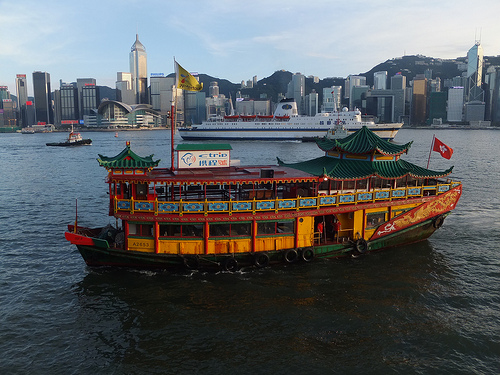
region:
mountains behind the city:
[55, 72, 490, 117]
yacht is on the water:
[187, 105, 406, 147]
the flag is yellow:
[173, 56, 203, 101]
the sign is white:
[174, 150, 228, 163]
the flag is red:
[436, 135, 456, 165]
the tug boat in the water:
[46, 125, 102, 161]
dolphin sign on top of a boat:
[167, 141, 243, 173]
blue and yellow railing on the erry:
[109, 187, 438, 203]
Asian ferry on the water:
[30, 55, 473, 296]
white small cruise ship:
[180, 83, 432, 150]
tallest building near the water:
[119, 28, 172, 127]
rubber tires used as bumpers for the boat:
[163, 231, 428, 270]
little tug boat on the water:
[43, 103, 108, 163]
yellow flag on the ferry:
[172, 60, 214, 107]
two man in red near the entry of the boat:
[305, 206, 379, 263]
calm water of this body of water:
[12, 261, 494, 371]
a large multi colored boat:
[63, 55, 463, 274]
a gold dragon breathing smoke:
[377, 187, 459, 234]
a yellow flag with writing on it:
[173, 58, 201, 93]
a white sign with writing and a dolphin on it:
[175, 143, 233, 168]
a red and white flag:
[430, 135, 452, 162]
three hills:
[176, 54, 499, 91]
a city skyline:
[0, 30, 496, 127]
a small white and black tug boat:
[47, 125, 92, 148]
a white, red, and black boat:
[177, 98, 401, 143]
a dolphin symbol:
[178, 150, 195, 167]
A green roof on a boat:
[316, 126, 414, 157]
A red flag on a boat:
[426, 135, 451, 165]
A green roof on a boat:
[95, 146, 160, 166]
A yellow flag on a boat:
[170, 61, 200, 87]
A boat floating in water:
[69, 131, 465, 273]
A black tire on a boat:
[356, 236, 369, 256]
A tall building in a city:
[127, 33, 147, 100]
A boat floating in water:
[45, 122, 92, 147]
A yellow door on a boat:
[295, 211, 312, 248]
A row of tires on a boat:
[212, 247, 310, 269]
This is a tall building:
[31, 63, 55, 130]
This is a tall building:
[49, 66, 81, 128]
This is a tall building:
[12, 65, 27, 133]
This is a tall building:
[124, 23, 152, 115]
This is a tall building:
[287, 65, 305, 115]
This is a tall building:
[322, 75, 344, 120]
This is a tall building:
[345, 62, 370, 115]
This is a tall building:
[389, 62, 405, 127]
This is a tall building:
[408, 68, 428, 125]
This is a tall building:
[467, 36, 487, 104]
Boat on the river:
[32, 103, 487, 278]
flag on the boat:
[423, 128, 456, 164]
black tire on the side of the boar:
[301, 241, 323, 266]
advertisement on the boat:
[181, 148, 231, 175]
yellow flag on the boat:
[165, 58, 209, 102]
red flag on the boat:
[421, 128, 455, 183]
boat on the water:
[57, 56, 467, 280]